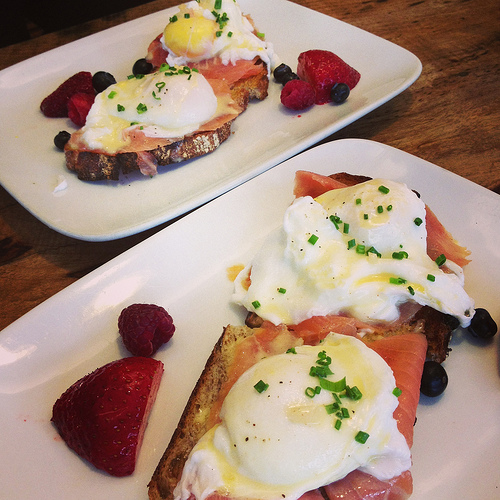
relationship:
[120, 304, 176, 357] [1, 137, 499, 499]
raspberry on plate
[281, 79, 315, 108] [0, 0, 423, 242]
raspberry on plate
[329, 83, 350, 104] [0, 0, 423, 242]
blueberry on plate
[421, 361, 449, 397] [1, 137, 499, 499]
blueberry on plate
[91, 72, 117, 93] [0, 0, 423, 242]
blueberry on plate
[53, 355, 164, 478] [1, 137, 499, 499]
strawberry on plate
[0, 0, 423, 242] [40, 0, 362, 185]
plate has food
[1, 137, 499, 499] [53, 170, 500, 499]
plate has food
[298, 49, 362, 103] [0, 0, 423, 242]
strawberry on top of plate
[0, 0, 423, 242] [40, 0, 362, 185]
plate underneath food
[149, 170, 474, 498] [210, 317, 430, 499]
sandwich has fish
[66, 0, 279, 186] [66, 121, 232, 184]
sandwich has crust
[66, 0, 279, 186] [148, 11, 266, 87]
sandwich has salmon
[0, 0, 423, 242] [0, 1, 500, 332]
plate on top of table